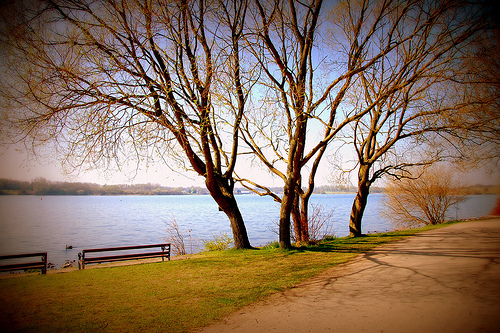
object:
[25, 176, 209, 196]
foot hills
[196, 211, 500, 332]
road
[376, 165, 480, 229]
tree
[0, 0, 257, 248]
tree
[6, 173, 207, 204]
trees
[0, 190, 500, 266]
lake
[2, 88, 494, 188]
clouds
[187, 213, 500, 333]
ground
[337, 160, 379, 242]
tree trunk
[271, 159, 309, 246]
tree trunk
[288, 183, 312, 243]
tree trunk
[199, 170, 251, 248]
tree trunk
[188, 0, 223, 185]
branches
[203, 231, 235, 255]
shrub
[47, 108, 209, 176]
branch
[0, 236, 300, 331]
green grassy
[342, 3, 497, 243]
tree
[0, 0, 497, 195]
sky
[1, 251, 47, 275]
bench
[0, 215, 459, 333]
grass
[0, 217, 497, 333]
land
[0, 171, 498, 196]
land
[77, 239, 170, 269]
bench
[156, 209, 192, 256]
plant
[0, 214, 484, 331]
lawn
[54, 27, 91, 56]
leaves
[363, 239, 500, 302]
shadow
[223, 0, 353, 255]
tree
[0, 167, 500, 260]
water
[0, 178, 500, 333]
area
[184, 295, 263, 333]
edge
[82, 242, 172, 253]
edge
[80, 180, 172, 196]
edge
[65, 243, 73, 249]
animal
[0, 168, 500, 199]
distance